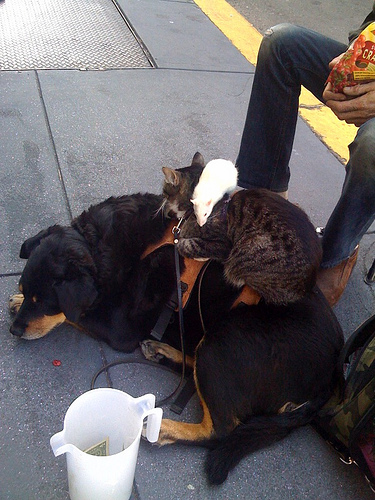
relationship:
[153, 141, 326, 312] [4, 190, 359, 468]
animal on top of animals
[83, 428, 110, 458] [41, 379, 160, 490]
bill on a pitcher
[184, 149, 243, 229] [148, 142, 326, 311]
mouse on cat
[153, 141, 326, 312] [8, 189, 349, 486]
animal on animal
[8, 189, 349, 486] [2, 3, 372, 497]
animal on sidewalk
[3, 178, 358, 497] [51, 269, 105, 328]
animal has ear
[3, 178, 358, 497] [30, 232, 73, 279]
animal has ear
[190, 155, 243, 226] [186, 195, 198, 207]
mouse has ear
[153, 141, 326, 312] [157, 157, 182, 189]
animal has ear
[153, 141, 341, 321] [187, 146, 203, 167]
animal has ear